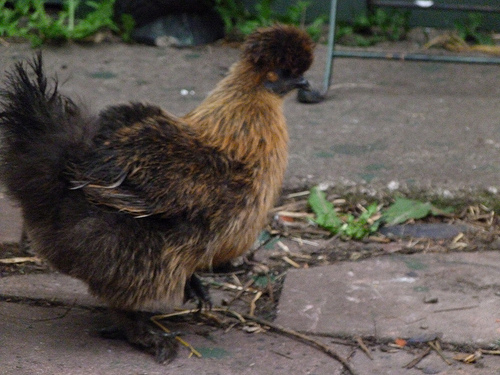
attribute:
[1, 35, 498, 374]
ground — concrete, dirty, broken, cracked, brown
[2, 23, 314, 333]
chicken — fancy, silky, brown, feathered, moptop hairdoed, small, hen, banty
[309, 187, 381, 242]
leaf — very green, broken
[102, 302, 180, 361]
foot — 5 toed, black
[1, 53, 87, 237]
tail — bit ruffled, feathered, black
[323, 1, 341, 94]
pole — metal, green, from chair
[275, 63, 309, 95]
face — black, tiny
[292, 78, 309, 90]
bill — dark blue grey, black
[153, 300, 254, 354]
straw — broken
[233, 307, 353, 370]
branch — broken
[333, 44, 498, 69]
bar — chair leg, green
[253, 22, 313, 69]
top knot — puffy